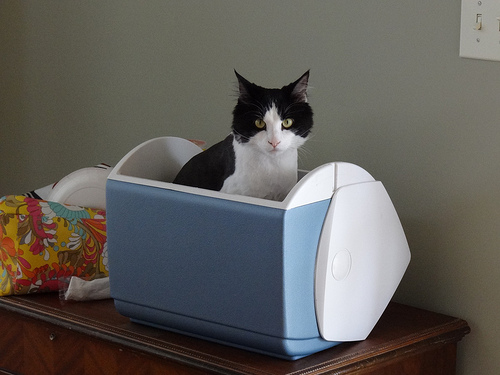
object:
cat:
[170, 66, 318, 201]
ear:
[282, 67, 313, 105]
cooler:
[103, 133, 416, 362]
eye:
[281, 116, 295, 130]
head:
[229, 67, 321, 159]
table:
[0, 289, 474, 375]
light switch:
[472, 13, 483, 31]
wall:
[0, 0, 499, 373]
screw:
[477, 0, 483, 7]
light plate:
[458, 0, 500, 62]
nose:
[267, 137, 282, 149]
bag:
[0, 193, 108, 295]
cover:
[314, 179, 412, 342]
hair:
[219, 98, 313, 202]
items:
[44, 165, 115, 209]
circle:
[331, 247, 354, 282]